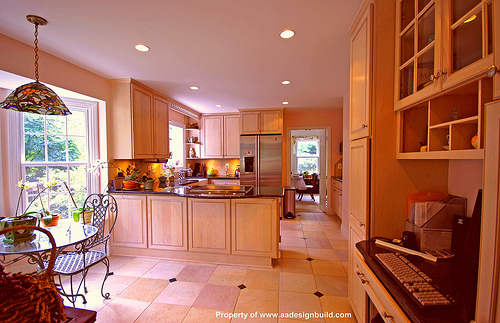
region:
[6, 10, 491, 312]
A large kitchen and dinette area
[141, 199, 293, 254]
Light brown wooden cabinets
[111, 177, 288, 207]
A dark brown counter top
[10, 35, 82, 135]
A hanging light over table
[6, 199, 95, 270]
Dinette table with chairs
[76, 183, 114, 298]
Metal chair with scroll design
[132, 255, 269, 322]
Large different color tiles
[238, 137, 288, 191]
A stainless steel refrigerator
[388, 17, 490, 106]
Cabinets with glass doors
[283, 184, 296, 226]
A stainless trash can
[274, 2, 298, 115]
recessed lighting hanging in the ceiling.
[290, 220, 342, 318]
A geometric pattern in the floor tile.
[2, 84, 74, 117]
a stained glass light fixture hung in the ceiling.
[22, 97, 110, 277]
A patio door leading out of the kitchen.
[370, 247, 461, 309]
An old computer keyboard on a desk.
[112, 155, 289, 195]
A lit up backsplash in a kitchen cove.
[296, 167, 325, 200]
A dining room in the background.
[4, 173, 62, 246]
Yellow flowers in green pot on a glass table.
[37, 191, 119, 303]
A wrought iron chair near a glass table.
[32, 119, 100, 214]
Shrubs outside the kitchen door.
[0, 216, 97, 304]
a round glass dining table in kitchen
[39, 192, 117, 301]
a wrought iron dining room chair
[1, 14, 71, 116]
a stain glass lamp hanging from ceiling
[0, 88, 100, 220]
kitchen window looking out on yard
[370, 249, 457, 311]
a computer keyboard on the desk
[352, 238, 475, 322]
a built in desk in the kitchen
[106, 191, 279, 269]
light colored wooden kitchen cabinets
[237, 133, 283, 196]
stainless steel refrigerator and freezer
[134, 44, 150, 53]
recessed lighting in the kitchen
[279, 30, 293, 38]
recessed lighting in the kitchen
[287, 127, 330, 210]
the door leaving the kitchen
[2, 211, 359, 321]
white tiles with black accent on kitchen floor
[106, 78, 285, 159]
light colored wooden kitchen cabinets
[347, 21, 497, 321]
light colored wooden kitchen cabinets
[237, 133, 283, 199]
a stainless steel refrigerator and freezer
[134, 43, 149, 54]
recessed kitchen lighting in the ceiling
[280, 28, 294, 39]
recessed kitchen lighting in the ceiling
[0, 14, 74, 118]
a stained glass lamp hanging from ceiling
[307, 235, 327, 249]
tan tile on floor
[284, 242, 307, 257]
tan tile on floor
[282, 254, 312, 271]
tan tile on floor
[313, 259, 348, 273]
tan tile on floor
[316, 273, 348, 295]
tan tile on floor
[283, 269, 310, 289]
tan tile on floor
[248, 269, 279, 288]
tan tile on floor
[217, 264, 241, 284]
tan tile on floor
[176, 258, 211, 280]
tan tile on floor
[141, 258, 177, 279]
tan tile on floor